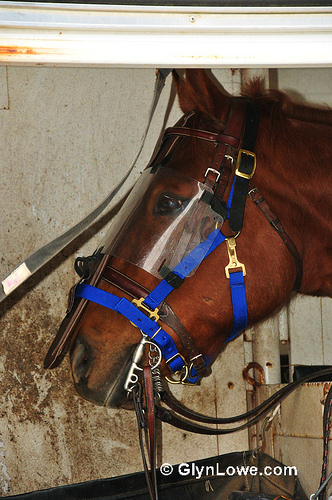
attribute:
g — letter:
[175, 459, 191, 479]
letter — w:
[235, 460, 250, 480]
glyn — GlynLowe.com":
[178, 461, 215, 479]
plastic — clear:
[93, 164, 224, 287]